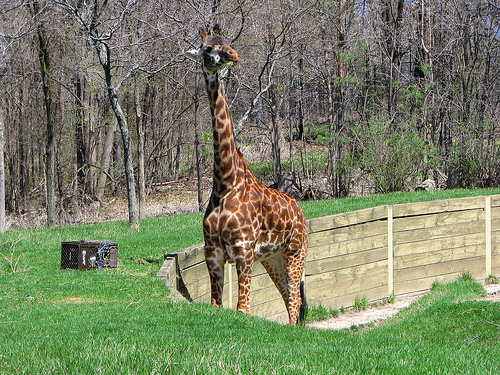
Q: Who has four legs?
A: The giraffe.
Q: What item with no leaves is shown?
A: A tree.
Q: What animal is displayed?
A: A giraffe.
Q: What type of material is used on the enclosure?
A: Wood.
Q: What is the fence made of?
A: Wood.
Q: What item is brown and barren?
A: Tree.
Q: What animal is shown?
A: A giraffe.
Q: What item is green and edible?
A: Grass.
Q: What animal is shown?
A: A giraffe.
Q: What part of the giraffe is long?
A: The neck.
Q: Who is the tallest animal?
A: The giraffe.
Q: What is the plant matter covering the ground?
A: Grass.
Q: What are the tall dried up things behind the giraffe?
A: A forest.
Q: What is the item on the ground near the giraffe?
A: A box.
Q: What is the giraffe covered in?
A: Spots.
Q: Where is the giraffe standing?
A: Near a brick wall.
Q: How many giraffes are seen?
A: One.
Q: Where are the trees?
A: In grass.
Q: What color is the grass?
A: Green.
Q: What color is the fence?
A: Tan.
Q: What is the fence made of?
A: Wood.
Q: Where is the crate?
A: In grass.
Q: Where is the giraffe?
A: Behind fence.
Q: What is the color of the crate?
A: Brown.